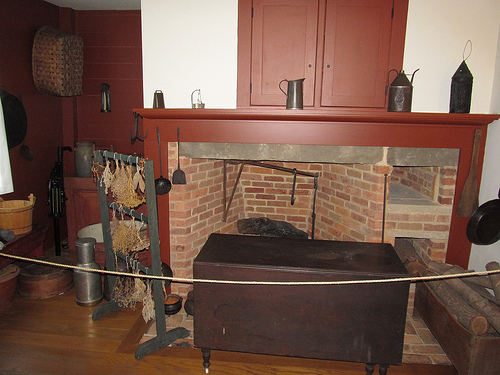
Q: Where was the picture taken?
A: At an exhibit.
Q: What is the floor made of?
A: Wood.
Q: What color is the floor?
A: Brown.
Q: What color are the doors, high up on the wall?
A: Red.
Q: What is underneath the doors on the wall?
A: A fireplace.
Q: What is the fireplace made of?
A: Brick.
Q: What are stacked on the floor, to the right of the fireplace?
A: Logs.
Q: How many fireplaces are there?
A: One.